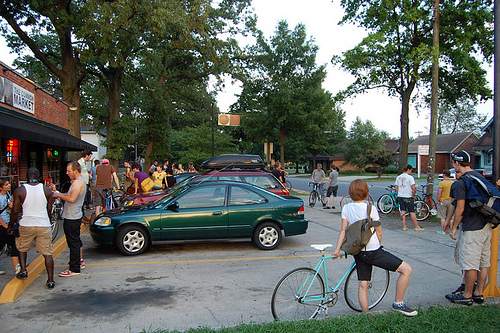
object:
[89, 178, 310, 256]
car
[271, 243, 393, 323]
bike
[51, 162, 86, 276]
people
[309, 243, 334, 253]
seat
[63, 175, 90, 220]
shirt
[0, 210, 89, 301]
curb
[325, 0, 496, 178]
tree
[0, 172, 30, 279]
lady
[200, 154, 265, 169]
carrier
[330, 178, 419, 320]
person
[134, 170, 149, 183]
shirt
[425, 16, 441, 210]
pole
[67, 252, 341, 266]
spot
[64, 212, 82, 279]
pants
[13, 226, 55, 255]
shorts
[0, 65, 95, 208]
market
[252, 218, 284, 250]
tire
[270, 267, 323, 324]
tire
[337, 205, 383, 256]
bag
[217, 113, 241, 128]
flag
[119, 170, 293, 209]
car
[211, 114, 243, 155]
sign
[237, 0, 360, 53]
sky